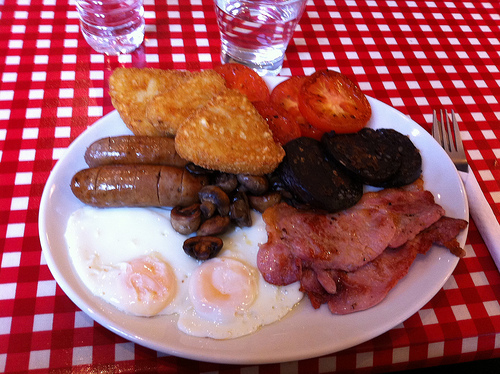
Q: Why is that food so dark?
A: It is burnt.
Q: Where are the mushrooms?
A: Center of the plate.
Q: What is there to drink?
A: Water.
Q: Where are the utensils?
A: Wrapped in a napkin.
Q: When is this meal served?
A: At breakfast.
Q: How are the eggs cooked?
A: Fried.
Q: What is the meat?
A: Ham.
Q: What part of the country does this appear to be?
A: The West.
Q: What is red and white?
A: The tablecloth.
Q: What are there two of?
A: Sausage links.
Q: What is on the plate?
A: Tomatoes.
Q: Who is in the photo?
A: No people.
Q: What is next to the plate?
A: A fork.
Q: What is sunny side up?
A: The eggs.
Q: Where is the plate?
A: Under the food.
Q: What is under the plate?
A: Red and white tablecloth.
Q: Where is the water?
A: In a glass.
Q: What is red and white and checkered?
A: The tablecloth.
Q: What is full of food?
A: The plate.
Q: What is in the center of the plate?
A: Cooked mushrooms.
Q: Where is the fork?
A: On the right side of the plate.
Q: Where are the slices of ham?
A: On the right side of the plate.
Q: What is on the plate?
A: Food.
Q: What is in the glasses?
A: Water.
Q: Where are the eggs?
A: In the bottom left corner.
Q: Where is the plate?
A: Red and white tablecloth.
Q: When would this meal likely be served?
A: Breakfast.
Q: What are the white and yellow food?
A: Eggs.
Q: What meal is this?
A: Breakfast.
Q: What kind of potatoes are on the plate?
A: Hash browns.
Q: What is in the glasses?
A: Water.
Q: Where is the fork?
A: Beside the plate.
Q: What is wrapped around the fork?
A: Napkin.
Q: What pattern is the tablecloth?
A: Red and white checkered.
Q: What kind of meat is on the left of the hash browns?
A: Sausages.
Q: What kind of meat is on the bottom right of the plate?
A: Ham.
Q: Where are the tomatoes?
A: On the top of the plate.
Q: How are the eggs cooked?
A: Over-easy.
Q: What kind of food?
A: Breakfast.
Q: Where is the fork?
A: To the right of the plate.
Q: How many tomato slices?
A: Four.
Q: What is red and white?
A: Tablecloth.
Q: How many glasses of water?
A: Two.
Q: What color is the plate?
A: White.